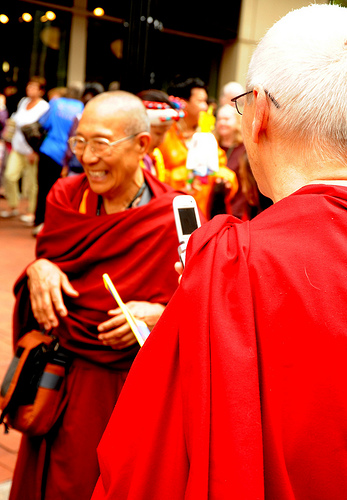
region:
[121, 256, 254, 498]
the clothing is red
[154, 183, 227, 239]
the phone is white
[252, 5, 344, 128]
the hair is white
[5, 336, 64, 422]
the bag is red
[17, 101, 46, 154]
the top is white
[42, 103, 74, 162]
the top is blue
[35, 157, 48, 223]
the pants are black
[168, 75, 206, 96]
the hair is black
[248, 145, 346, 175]
the skin is brown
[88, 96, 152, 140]
the head is bald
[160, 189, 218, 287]
man holding a flip phone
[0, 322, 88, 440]
orange bag on the man's side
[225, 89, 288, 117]
man wearing glasses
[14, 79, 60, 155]
woman wearing a white t shirt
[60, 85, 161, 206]
man is laughing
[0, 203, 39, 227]
woman wearing white shoes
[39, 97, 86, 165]
blue t shirt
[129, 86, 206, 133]
woman wearing an elegant head dress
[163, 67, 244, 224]
woman wearing bright and orange colors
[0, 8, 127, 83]
lights reflecting off the building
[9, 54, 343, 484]
two monks laughing together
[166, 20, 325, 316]
a month holding a cell phone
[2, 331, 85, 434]
an orange bag carried by a monk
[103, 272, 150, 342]
a yellow pen held by a monk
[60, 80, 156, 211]
glasses sit on the face of a man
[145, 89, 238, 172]
a crowd gathering in the background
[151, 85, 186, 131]
a woman is wearing a head dress with flowers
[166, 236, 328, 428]
a bright red cloak worn by a monk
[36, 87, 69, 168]
a blue shirt covering a person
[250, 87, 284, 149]
an ear on the head of a man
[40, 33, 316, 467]
men in a crowd smiling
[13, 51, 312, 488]
men wearing draped robes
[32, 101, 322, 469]
men wearing red religious garments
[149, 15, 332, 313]
man checking white cellphone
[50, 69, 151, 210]
man with eyeglasses laughing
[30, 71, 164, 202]
man with bald head looking to side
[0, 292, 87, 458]
red and black case hanging from waist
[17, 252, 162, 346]
hands in front of body above waist level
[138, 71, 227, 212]
couple in colorful costumes passing in front of crowd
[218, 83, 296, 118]
eyeglasses on man's head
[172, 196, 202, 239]
Top of the white cell phone held by the monk.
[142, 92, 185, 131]
Lady wearing a head wrap behind the monk facing the camera.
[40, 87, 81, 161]
Person wearing a light blue shirt.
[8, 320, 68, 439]
Orange and black bag being carried by the monk facing the camera.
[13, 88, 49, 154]
Person wearing the white t-shirt in the background.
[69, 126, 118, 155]
Glasses on the person smiling in the red long cape.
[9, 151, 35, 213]
Beige pants worn by the person wearing a white t-shirt.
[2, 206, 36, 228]
White shoes worn by the person wearing beige pants.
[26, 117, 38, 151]
Brown purse being held by the person in the blue shirt.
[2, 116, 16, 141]
Light brown bag held by the person in the white shirt and beige pants.